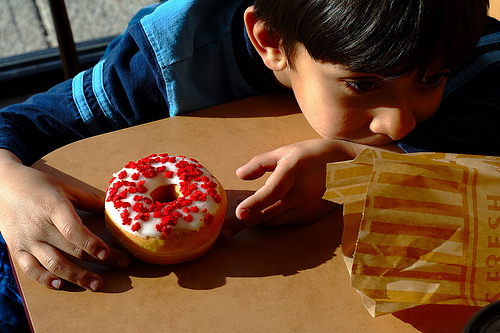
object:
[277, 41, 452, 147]
face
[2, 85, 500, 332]
table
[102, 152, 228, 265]
doughnut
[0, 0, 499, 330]
boy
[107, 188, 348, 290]
sun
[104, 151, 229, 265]
donut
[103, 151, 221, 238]
sprinkle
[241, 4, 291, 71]
ear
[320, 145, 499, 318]
bag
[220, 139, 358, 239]
hands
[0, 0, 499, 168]
shirt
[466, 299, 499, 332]
lid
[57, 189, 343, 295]
shadow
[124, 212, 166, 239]
frosting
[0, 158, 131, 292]
hand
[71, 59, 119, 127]
stripes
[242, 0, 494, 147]
head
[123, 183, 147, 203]
frosting